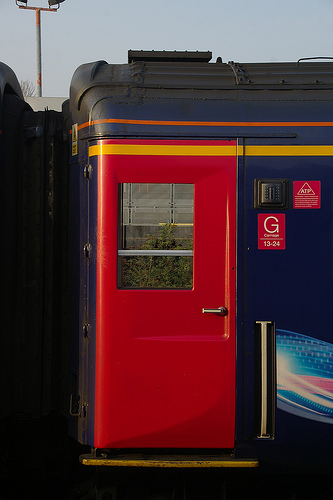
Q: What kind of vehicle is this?
A: A train.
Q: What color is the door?
A: Red.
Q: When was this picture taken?
A: The daytime.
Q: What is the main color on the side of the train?
A: Blue.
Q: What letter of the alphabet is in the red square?
A: 'G'.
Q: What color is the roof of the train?
A: Black.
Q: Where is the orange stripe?
A: Above the door.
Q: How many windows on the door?
A: One.